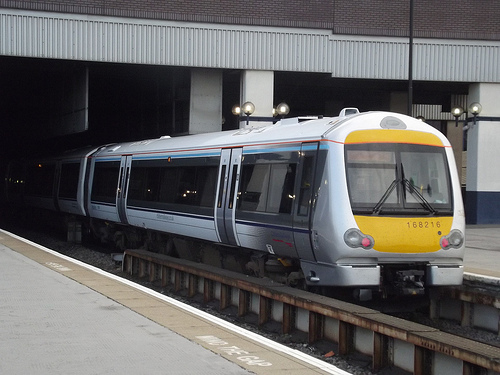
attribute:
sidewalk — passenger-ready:
[472, 206, 497, 261]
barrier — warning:
[182, 231, 410, 368]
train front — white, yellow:
[325, 111, 466, 300]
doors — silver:
[112, 141, 243, 251]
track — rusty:
[6, 247, 498, 366]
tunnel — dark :
[1, 47, 482, 217]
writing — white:
[193, 321, 274, 371]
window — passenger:
[124, 155, 220, 220]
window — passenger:
[231, 147, 299, 219]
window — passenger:
[87, 157, 122, 208]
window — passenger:
[52, 158, 83, 200]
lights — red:
[334, 220, 472, 265]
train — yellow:
[284, 97, 389, 266]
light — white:
[343, 226, 377, 256]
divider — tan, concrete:
[123, 247, 498, 373]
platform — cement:
[1, 233, 354, 373]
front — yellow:
[342, 125, 461, 256]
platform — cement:
[465, 224, 499, 283]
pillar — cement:
[232, 70, 279, 130]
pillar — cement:
[466, 84, 499, 189]